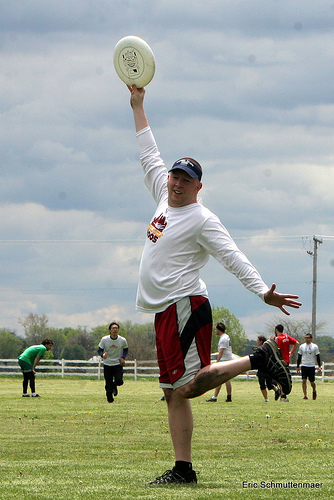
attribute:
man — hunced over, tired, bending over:
[17, 338, 53, 400]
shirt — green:
[18, 344, 48, 367]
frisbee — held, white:
[113, 36, 156, 89]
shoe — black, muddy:
[148, 470, 198, 488]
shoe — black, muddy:
[252, 337, 294, 397]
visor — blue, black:
[168, 158, 202, 182]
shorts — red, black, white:
[154, 294, 214, 390]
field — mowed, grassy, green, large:
[0, 380, 332, 499]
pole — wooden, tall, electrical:
[307, 234, 324, 346]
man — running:
[97, 322, 131, 404]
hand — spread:
[263, 283, 303, 317]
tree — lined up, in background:
[17, 312, 50, 348]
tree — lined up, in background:
[211, 305, 248, 358]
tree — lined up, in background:
[262, 314, 324, 365]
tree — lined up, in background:
[0, 327, 27, 359]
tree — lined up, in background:
[59, 342, 87, 371]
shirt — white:
[98, 336, 130, 369]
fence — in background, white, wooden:
[2, 359, 334, 384]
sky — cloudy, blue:
[0, 1, 333, 341]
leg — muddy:
[162, 386, 194, 463]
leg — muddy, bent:
[175, 355, 252, 400]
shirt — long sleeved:
[95, 348, 127, 359]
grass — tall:
[1, 373, 332, 383]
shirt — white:
[297, 343, 321, 369]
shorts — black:
[301, 366, 317, 382]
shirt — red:
[275, 335, 298, 364]